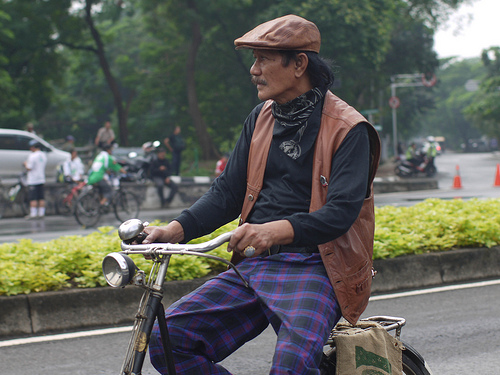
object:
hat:
[230, 13, 322, 54]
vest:
[236, 98, 381, 328]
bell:
[116, 216, 149, 246]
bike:
[99, 217, 436, 373]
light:
[101, 252, 134, 291]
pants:
[150, 245, 345, 374]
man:
[132, 10, 380, 374]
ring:
[243, 245, 257, 257]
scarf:
[267, 88, 322, 162]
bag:
[325, 314, 411, 372]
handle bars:
[116, 217, 241, 260]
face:
[246, 50, 280, 99]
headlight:
[100, 251, 140, 288]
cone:
[450, 162, 464, 191]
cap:
[234, 14, 322, 54]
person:
[88, 139, 127, 209]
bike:
[73, 172, 141, 227]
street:
[423, 136, 500, 193]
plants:
[387, 197, 499, 246]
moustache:
[248, 76, 269, 86]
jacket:
[210, 98, 379, 330]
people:
[148, 140, 183, 210]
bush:
[0, 198, 497, 284]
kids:
[21, 139, 49, 221]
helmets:
[27, 139, 41, 147]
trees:
[4, 2, 188, 171]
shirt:
[173, 103, 372, 256]